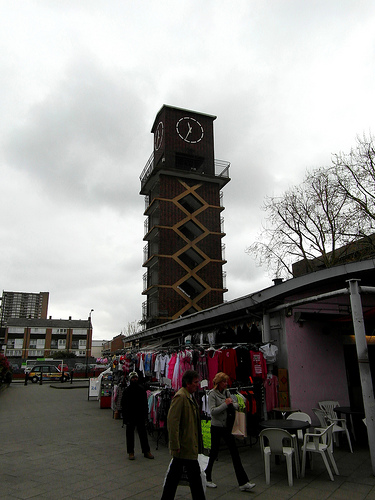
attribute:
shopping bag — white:
[161, 452, 210, 494]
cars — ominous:
[25, 42, 120, 139]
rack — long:
[94, 341, 293, 396]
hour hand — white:
[187, 120, 192, 131]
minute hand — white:
[182, 129, 191, 138]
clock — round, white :
[174, 116, 207, 141]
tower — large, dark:
[160, 93, 252, 166]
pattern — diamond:
[168, 175, 216, 279]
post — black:
[22, 371, 27, 384]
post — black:
[38, 371, 43, 384]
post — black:
[60, 370, 64, 381]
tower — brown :
[134, 98, 232, 328]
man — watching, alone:
[116, 370, 156, 461]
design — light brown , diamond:
[173, 175, 211, 318]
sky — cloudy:
[24, 25, 330, 76]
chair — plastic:
[254, 426, 299, 486]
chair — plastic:
[299, 419, 341, 483]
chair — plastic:
[282, 408, 311, 441]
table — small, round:
[261, 413, 310, 468]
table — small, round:
[332, 401, 360, 439]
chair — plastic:
[311, 406, 354, 454]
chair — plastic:
[318, 398, 345, 422]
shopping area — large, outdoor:
[100, 317, 367, 476]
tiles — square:
[70, 431, 127, 481]